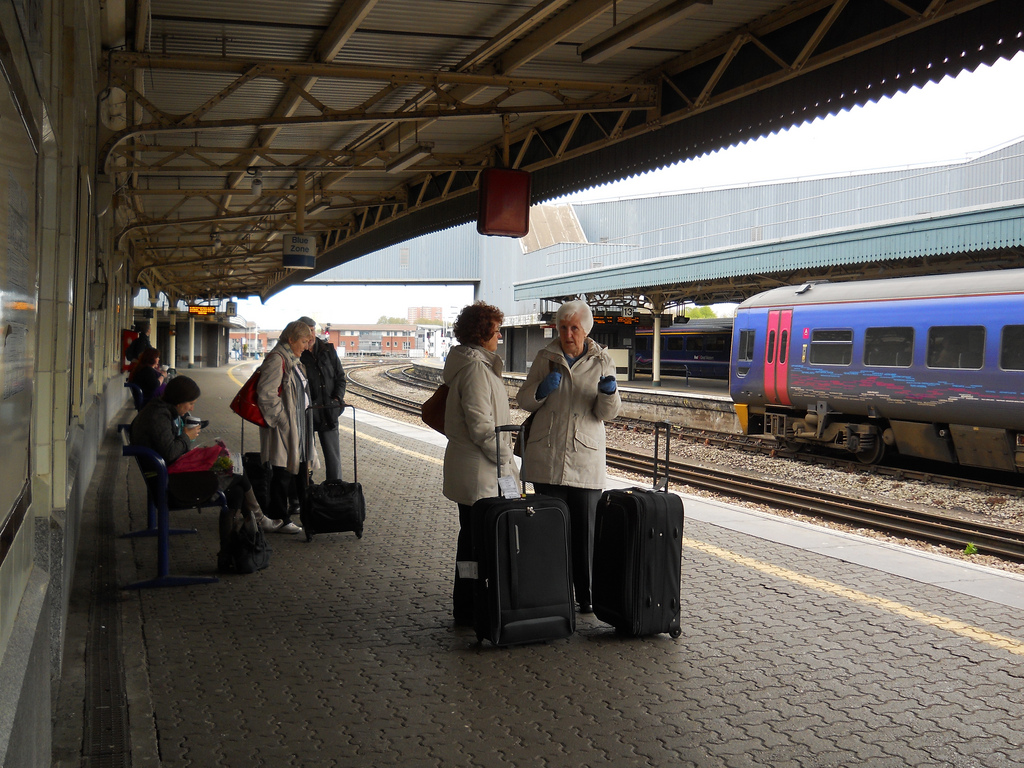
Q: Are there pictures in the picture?
A: No, there are no pictures.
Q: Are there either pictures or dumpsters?
A: No, there are no pictures or dumpsters.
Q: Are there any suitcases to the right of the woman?
A: Yes, there is a suitcase to the right of the woman.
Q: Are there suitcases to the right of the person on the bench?
A: Yes, there is a suitcase to the right of the woman.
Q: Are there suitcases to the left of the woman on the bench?
A: No, the suitcase is to the right of the woman.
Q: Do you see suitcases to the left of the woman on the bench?
A: No, the suitcase is to the right of the woman.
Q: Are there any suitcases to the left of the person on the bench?
A: No, the suitcase is to the right of the woman.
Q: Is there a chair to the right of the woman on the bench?
A: No, there is a suitcase to the right of the woman.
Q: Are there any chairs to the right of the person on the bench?
A: No, there is a suitcase to the right of the woman.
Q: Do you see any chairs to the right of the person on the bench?
A: No, there is a suitcase to the right of the woman.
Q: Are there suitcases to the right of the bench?
A: Yes, there is a suitcase to the right of the bench.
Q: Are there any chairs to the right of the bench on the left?
A: No, there is a suitcase to the right of the bench.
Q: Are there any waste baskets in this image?
A: No, there are no waste baskets.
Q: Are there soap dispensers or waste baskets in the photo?
A: No, there are no waste baskets or soap dispensers.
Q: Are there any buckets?
A: No, there are no buckets.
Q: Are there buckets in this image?
A: No, there are no buckets.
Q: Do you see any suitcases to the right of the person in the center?
A: Yes, there is a suitcase to the right of the person.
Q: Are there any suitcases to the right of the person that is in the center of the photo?
A: Yes, there is a suitcase to the right of the person.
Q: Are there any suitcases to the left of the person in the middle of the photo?
A: No, the suitcase is to the right of the person.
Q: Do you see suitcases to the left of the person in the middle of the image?
A: No, the suitcase is to the right of the person.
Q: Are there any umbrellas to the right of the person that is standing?
A: No, there is a suitcase to the right of the person.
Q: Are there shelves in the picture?
A: No, there are no shelves.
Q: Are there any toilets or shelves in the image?
A: No, there are no shelves or toilets.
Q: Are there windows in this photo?
A: Yes, there is a window.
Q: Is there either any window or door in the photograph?
A: Yes, there is a window.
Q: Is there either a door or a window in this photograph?
A: Yes, there is a window.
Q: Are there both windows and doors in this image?
A: Yes, there are both a window and doors.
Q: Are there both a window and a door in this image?
A: Yes, there are both a window and a door.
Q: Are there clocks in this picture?
A: No, there are no clocks.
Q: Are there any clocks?
A: No, there are no clocks.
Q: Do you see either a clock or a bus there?
A: No, there are no clocks or buses.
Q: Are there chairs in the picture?
A: No, there are no chairs.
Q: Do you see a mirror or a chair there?
A: No, there are no chairs or mirrors.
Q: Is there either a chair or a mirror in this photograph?
A: No, there are no chairs or mirrors.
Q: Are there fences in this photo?
A: No, there are no fences.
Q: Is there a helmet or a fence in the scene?
A: No, there are no fences or helmets.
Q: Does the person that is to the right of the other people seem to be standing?
A: Yes, the person is standing.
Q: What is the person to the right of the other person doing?
A: The person is standing.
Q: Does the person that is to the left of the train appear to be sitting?
A: No, the person is standing.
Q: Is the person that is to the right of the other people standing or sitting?
A: The person is standing.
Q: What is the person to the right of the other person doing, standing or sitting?
A: The person is standing.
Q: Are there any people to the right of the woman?
A: Yes, there is a person to the right of the woman.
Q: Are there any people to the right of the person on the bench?
A: Yes, there is a person to the right of the woman.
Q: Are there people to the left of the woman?
A: No, the person is to the right of the woman.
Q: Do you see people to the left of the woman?
A: No, the person is to the right of the woman.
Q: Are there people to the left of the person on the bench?
A: No, the person is to the right of the woman.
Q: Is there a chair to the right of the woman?
A: No, there is a person to the right of the woman.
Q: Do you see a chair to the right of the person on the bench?
A: No, there is a person to the right of the woman.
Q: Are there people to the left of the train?
A: Yes, there is a person to the left of the train.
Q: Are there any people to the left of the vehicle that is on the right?
A: Yes, there is a person to the left of the train.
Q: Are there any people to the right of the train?
A: No, the person is to the left of the train.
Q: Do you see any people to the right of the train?
A: No, the person is to the left of the train.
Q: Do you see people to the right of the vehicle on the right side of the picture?
A: No, the person is to the left of the train.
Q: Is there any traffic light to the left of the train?
A: No, there is a person to the left of the train.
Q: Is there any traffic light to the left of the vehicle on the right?
A: No, there is a person to the left of the train.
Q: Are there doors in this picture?
A: Yes, there are doors.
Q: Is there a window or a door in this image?
A: Yes, there are doors.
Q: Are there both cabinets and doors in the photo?
A: No, there are doors but no cabinets.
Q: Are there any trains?
A: Yes, there is a train.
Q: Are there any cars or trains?
A: Yes, there is a train.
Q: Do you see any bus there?
A: No, there are no buses.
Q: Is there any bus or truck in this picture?
A: No, there are no buses or trucks.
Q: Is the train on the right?
A: Yes, the train is on the right of the image.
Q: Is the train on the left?
A: No, the train is on the right of the image.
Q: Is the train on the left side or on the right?
A: The train is on the right of the image.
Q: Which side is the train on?
A: The train is on the right of the image.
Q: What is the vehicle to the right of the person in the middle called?
A: The vehicle is a train.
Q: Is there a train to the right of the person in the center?
A: Yes, there is a train to the right of the person.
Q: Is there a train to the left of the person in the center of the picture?
A: No, the train is to the right of the person.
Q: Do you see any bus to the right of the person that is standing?
A: No, there is a train to the right of the person.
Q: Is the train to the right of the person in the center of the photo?
A: Yes, the train is to the right of the person.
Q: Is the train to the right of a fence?
A: No, the train is to the right of the person.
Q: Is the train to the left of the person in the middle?
A: No, the train is to the right of the person.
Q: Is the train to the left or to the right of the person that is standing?
A: The train is to the right of the person.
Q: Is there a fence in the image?
A: No, there are no fences.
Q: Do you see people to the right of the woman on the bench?
A: Yes, there is a person to the right of the woman.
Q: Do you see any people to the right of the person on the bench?
A: Yes, there is a person to the right of the woman.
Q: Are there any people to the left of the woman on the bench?
A: No, the person is to the right of the woman.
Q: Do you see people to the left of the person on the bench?
A: No, the person is to the right of the woman.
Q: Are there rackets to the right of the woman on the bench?
A: No, there is a person to the right of the woman.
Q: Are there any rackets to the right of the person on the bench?
A: No, there is a person to the right of the woman.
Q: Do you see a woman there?
A: Yes, there is a woman.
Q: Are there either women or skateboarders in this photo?
A: Yes, there is a woman.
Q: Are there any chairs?
A: No, there are no chairs.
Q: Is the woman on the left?
A: Yes, the woman is on the left of the image.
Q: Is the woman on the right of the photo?
A: No, the woman is on the left of the image.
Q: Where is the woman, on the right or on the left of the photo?
A: The woman is on the left of the image.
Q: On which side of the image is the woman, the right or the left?
A: The woman is on the left of the image.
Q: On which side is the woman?
A: The woman is on the left of the image.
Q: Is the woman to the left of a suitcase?
A: Yes, the woman is to the left of a suitcase.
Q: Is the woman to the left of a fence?
A: No, the woman is to the left of a suitcase.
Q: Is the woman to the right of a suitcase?
A: No, the woman is to the left of a suitcase.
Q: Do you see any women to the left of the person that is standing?
A: Yes, there is a woman to the left of the person.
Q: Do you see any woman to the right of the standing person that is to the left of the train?
A: No, the woman is to the left of the person.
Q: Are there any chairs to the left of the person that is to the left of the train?
A: No, there is a woman to the left of the person.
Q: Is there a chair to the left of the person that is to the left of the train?
A: No, there is a woman to the left of the person.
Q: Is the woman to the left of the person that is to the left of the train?
A: Yes, the woman is to the left of the person.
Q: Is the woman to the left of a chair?
A: No, the woman is to the left of the person.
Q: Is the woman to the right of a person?
A: No, the woman is to the left of a person.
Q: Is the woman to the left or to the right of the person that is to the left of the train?
A: The woman is to the left of the person.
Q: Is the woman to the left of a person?
A: Yes, the woman is to the left of a person.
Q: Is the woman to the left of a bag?
A: No, the woman is to the left of a person.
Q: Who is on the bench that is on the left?
A: The woman is on the bench.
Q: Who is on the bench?
A: The woman is on the bench.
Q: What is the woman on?
A: The woman is on the bench.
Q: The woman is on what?
A: The woman is on the bench.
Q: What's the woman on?
A: The woman is on the bench.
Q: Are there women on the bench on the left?
A: Yes, there is a woman on the bench.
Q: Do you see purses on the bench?
A: No, there is a woman on the bench.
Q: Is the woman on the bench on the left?
A: Yes, the woman is on the bench.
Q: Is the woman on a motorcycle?
A: No, the woman is on the bench.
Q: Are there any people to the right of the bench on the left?
A: Yes, there are people to the right of the bench.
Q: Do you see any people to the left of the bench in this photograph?
A: No, the people are to the right of the bench.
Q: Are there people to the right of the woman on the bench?
A: Yes, there are people to the right of the woman.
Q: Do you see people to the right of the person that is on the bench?
A: Yes, there are people to the right of the woman.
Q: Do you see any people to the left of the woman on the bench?
A: No, the people are to the right of the woman.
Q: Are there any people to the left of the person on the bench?
A: No, the people are to the right of the woman.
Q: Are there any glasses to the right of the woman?
A: No, there are people to the right of the woman.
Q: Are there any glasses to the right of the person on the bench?
A: No, there are people to the right of the woman.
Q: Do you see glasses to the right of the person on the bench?
A: No, there are people to the right of the woman.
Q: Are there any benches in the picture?
A: Yes, there is a bench.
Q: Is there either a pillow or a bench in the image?
A: Yes, there is a bench.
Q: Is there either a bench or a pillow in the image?
A: Yes, there is a bench.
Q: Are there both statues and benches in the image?
A: No, there is a bench but no statues.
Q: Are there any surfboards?
A: No, there are no surfboards.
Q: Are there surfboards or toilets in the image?
A: No, there are no surfboards or toilets.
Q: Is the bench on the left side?
A: Yes, the bench is on the left of the image.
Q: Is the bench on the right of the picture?
A: No, the bench is on the left of the image.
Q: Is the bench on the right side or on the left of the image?
A: The bench is on the left of the image.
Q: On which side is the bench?
A: The bench is on the left of the image.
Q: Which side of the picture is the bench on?
A: The bench is on the left of the image.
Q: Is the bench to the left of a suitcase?
A: Yes, the bench is to the left of a suitcase.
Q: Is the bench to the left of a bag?
A: No, the bench is to the left of a suitcase.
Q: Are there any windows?
A: Yes, there is a window.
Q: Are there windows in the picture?
A: Yes, there is a window.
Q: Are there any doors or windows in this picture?
A: Yes, there is a window.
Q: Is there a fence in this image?
A: No, there are no fences.